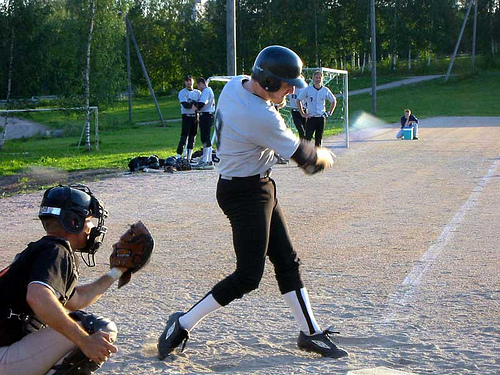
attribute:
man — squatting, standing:
[153, 37, 371, 373]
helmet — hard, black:
[238, 39, 308, 90]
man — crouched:
[396, 109, 424, 140]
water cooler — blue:
[402, 127, 417, 141]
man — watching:
[302, 70, 337, 142]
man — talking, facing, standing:
[187, 77, 219, 166]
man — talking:
[174, 71, 196, 162]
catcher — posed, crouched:
[6, 179, 154, 368]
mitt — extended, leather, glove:
[108, 221, 153, 277]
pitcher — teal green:
[398, 127, 414, 142]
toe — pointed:
[162, 352, 168, 356]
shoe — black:
[159, 307, 186, 361]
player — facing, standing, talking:
[179, 78, 204, 162]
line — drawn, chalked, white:
[405, 163, 498, 302]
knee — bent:
[234, 273, 256, 288]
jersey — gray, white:
[216, 81, 289, 175]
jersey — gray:
[178, 87, 204, 116]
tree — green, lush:
[46, 6, 122, 117]